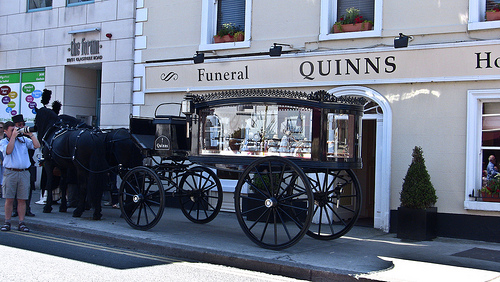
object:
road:
[1, 212, 498, 282]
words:
[160, 51, 500, 81]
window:
[210, 0, 245, 43]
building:
[1, 0, 136, 188]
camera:
[16, 125, 36, 136]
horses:
[58, 114, 136, 220]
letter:
[364, 57, 380, 74]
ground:
[0, 65, 500, 282]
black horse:
[34, 105, 139, 219]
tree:
[395, 145, 438, 211]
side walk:
[0, 190, 500, 282]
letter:
[317, 59, 332, 75]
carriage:
[118, 89, 363, 250]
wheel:
[234, 155, 314, 250]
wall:
[182, 88, 324, 167]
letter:
[198, 65, 250, 81]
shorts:
[1, 169, 30, 201]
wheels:
[124, 155, 364, 250]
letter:
[334, 59, 341, 76]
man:
[0, 119, 48, 235]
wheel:
[286, 169, 364, 241]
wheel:
[117, 166, 167, 230]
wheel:
[175, 166, 223, 223]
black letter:
[215, 72, 222, 80]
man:
[0, 114, 39, 218]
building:
[138, 0, 500, 239]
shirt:
[0, 137, 33, 169]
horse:
[34, 106, 111, 221]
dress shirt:
[0, 136, 35, 169]